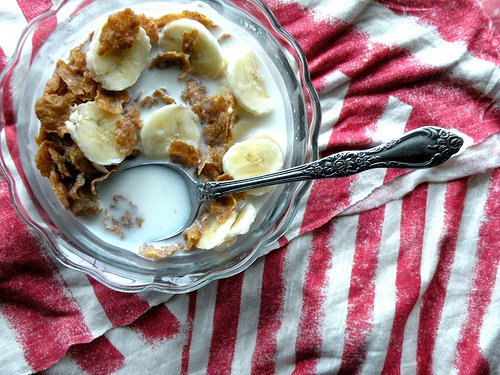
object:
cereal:
[163, 139, 200, 167]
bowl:
[0, 0, 322, 293]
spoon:
[117, 124, 463, 241]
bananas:
[64, 97, 137, 169]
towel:
[0, 0, 499, 375]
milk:
[29, 0, 289, 259]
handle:
[203, 123, 462, 197]